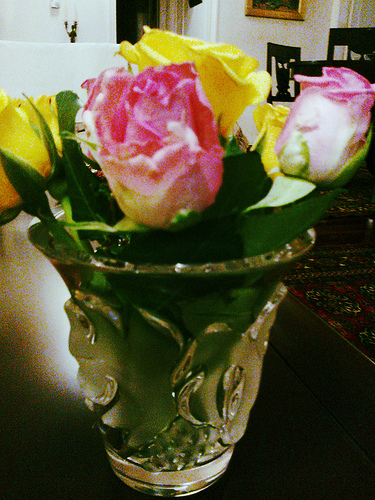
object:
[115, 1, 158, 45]
doorway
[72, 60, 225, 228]
flower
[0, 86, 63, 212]
flower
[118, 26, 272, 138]
flower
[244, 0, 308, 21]
frame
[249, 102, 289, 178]
flowers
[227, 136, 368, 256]
leaves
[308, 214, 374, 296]
floor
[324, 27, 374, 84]
chair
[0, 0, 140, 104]
wall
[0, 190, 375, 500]
table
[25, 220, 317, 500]
flower pot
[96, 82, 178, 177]
pink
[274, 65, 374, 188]
flower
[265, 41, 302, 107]
chair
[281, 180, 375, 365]
carpet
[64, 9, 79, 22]
candles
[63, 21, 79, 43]
candle holder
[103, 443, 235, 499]
bottom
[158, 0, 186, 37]
curtains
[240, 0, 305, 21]
picture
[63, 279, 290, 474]
images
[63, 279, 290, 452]
design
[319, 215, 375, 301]
ground